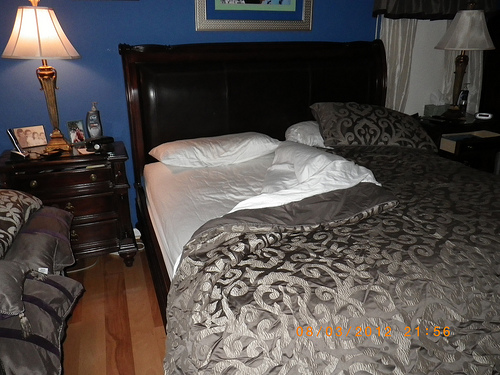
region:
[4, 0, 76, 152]
Light on the table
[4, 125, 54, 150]
Black and white picture on the table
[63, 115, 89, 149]
Colored picture on the table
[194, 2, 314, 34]
Picture on the wall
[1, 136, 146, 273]
Dark brown wood bedstand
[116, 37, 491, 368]
Bed with leather bedhead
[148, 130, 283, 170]
White pillow on the bed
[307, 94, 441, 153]
Gray and silver pillow on the bed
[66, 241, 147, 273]
Gray electric wire on the floor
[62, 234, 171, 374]
wood floor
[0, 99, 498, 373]
bedroom with gray and black linens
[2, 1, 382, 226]
wall painted royal blue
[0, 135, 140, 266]
dark brown bedside table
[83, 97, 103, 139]
bottle of hand lotion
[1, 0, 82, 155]
lamp with white shade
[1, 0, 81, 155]
lamp is turned on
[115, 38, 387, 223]
dark brown sleighbed headboard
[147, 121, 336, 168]
white pillows on bed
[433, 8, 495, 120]
lamp is turned off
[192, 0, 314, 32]
bottom of art on wall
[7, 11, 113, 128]
the light is on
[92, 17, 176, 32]
the light is blue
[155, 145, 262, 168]
the bed sheet is white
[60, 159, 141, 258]
the cabinet is brown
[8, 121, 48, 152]
there is photo on the cabinet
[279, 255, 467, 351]
the blanket is silver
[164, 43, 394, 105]
the headboard is black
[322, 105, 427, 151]
the pillows are grey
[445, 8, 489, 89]
the lamp is off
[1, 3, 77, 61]
lit up lamp shade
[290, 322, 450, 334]
date time stamp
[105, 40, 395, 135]
top of dark wooden head board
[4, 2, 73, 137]
the turned on lamp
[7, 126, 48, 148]
picture frame on night stand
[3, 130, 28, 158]
cordless phone on night stand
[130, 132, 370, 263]
unmade side of the bed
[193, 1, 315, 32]
silver frame hanging on wall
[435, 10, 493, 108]
lamp not turned on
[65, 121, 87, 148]
smaller picture frame on night stand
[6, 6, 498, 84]
Two lamps are seen.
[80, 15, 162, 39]
Wall is blue color.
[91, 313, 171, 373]
Floor is brown color.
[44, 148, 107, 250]
Side table is brown color.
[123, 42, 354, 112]
Cot is brown color.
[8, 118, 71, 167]
Photo is in the side table.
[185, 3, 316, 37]
Picture is hanging in the wall.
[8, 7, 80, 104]
One lamp is on.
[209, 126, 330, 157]
Two white pillows are there.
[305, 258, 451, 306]
Quilt is grey color.